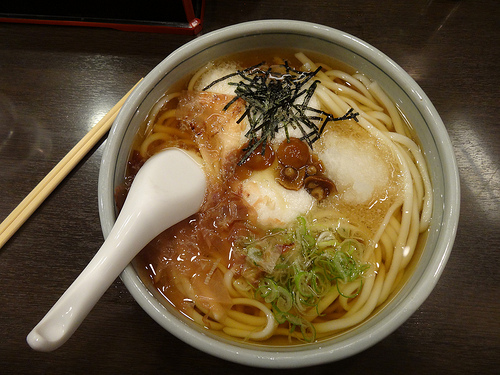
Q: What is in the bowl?
A: Food.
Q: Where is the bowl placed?
A: On a table.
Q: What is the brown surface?
A: Table.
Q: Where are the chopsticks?
A: On table.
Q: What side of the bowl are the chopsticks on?
A: The left.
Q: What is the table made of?
A: Wood.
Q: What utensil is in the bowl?
A: Spoon.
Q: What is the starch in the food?
A: Noodles.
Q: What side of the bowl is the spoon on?
A: The left.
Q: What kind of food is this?
A: Soup.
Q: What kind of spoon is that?
A: Chinese spoon.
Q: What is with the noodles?
A: Veggies.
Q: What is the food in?
A: Bowl.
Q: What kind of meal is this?
A: Soup.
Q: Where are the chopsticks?
A: Table.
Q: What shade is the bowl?
A: Light.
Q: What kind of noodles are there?
A: Ramen.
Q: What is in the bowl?
A: Noodles.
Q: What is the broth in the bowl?
A: Soup broth.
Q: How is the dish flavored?
A: With scallions.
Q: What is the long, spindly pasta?
A: Noodles.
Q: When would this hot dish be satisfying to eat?
A: Winter.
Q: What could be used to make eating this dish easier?
A: Smaller spoon.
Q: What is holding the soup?
A: A bowl.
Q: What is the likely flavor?
A: Beef.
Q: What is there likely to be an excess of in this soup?
A: Salt.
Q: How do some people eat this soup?
A: With chopsticks.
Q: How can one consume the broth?
A: Drink it.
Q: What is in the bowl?
A: Food.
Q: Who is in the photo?
A: No one.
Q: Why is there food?
A: For people to eat.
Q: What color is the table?
A: Brown.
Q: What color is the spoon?
A: White.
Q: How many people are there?
A: None.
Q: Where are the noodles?
A: In the bowl.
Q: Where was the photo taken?
A: Next to noodles.